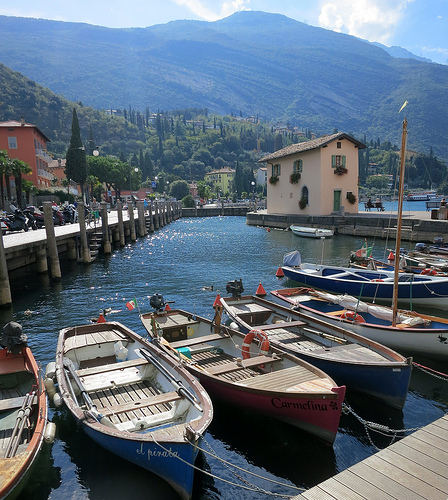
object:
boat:
[52, 322, 215, 498]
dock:
[0, 120, 448, 500]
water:
[180, 217, 259, 281]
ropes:
[342, 404, 420, 440]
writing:
[136, 443, 181, 460]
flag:
[125, 298, 141, 316]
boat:
[138, 306, 343, 446]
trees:
[145, 151, 154, 176]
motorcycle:
[1, 209, 28, 235]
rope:
[186, 438, 304, 492]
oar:
[63, 356, 96, 415]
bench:
[426, 201, 446, 211]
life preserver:
[242, 328, 270, 369]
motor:
[150, 293, 175, 312]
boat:
[271, 281, 448, 356]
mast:
[390, 119, 407, 327]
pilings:
[76, 204, 91, 264]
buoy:
[267, 228, 271, 232]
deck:
[296, 414, 448, 500]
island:
[4, 0, 448, 500]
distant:
[9, 16, 436, 70]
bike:
[28, 205, 64, 229]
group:
[4, 197, 104, 233]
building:
[258, 132, 367, 214]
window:
[332, 155, 341, 167]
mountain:
[0, 9, 448, 193]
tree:
[65, 108, 86, 204]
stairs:
[82, 231, 102, 265]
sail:
[305, 289, 421, 325]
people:
[375, 198, 385, 211]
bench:
[364, 202, 384, 212]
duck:
[203, 284, 214, 292]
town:
[1, 118, 441, 337]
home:
[115, 104, 267, 136]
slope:
[0, 62, 233, 184]